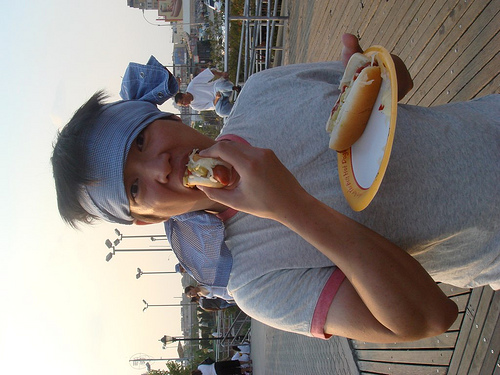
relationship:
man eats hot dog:
[51, 61, 500, 344] [319, 48, 385, 156]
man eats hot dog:
[51, 61, 495, 333] [170, 125, 224, 201]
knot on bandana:
[108, 55, 180, 102] [76, 55, 227, 287]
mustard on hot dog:
[181, 164, 217, 184] [185, 147, 237, 194]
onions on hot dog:
[186, 157, 221, 197] [181, 164, 220, 182]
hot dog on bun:
[180, 151, 234, 189] [184, 148, 231, 188]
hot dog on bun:
[322, 50, 383, 153] [325, 51, 385, 151]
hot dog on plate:
[322, 52, 381, 154] [330, 52, 414, 217]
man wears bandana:
[51, 61, 500, 344] [55, 51, 172, 236]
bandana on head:
[55, 51, 172, 236] [50, 68, 225, 238]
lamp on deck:
[148, 317, 225, 367] [258, 16, 499, 341]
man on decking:
[51, 61, 500, 344] [323, 25, 494, 81]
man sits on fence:
[161, 68, 233, 115] [224, 12, 279, 72]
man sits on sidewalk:
[171, 68, 236, 119] [201, 30, 317, 80]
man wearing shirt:
[51, 61, 500, 344] [224, 62, 500, 340]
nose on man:
[147, 148, 176, 183] [55, 47, 442, 334]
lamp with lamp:
[104, 229, 247, 363] [81, 212, 263, 374]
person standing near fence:
[184, 356, 255, 373] [224, 0, 280, 92]